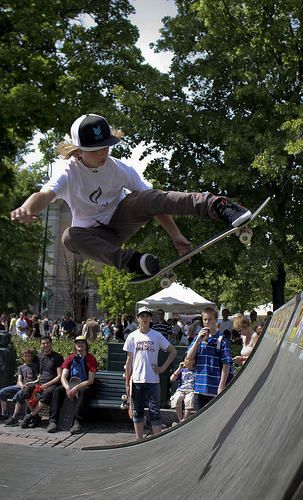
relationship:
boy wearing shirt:
[11, 112, 251, 272] [43, 158, 148, 230]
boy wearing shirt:
[50, 335, 97, 436] [60, 355, 99, 377]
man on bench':
[170, 353, 198, 424] [78, 371, 173, 407]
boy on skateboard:
[11, 112, 251, 272] [127, 197, 272, 285]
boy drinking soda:
[183, 306, 232, 411] [199, 327, 209, 344]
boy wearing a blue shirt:
[183, 306, 232, 411] [184, 332, 231, 398]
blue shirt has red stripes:
[184, 332, 231, 398] [193, 337, 231, 394]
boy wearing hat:
[11, 112, 251, 272] [69, 112, 120, 152]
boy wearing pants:
[11, 112, 251, 272] [63, 188, 223, 269]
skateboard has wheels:
[127, 197, 272, 285] [160, 231, 252, 291]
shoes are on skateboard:
[134, 200, 248, 273] [127, 197, 272, 285]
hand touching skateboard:
[173, 236, 196, 263] [127, 197, 272, 285]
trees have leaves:
[2, 3, 301, 316] [2, 2, 299, 299]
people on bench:
[5, 336, 200, 433] [83, 371, 135, 409]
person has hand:
[122, 306, 178, 440] [149, 361, 163, 377]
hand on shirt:
[149, 361, 163, 377] [121, 330, 170, 382]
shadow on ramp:
[199, 297, 302, 479] [4, 295, 301, 498]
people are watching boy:
[5, 336, 200, 433] [11, 112, 251, 272]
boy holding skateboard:
[11, 112, 251, 272] [127, 197, 272, 285]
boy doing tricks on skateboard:
[11, 112, 251, 272] [127, 197, 272, 285]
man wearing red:
[170, 353, 198, 424] [60, 355, 99, 377]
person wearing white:
[122, 306, 178, 440] [121, 330, 170, 382]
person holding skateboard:
[122, 306, 178, 440] [120, 364, 134, 422]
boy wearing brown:
[11, 112, 251, 272] [63, 188, 223, 269]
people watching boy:
[5, 336, 200, 433] [11, 112, 251, 272]